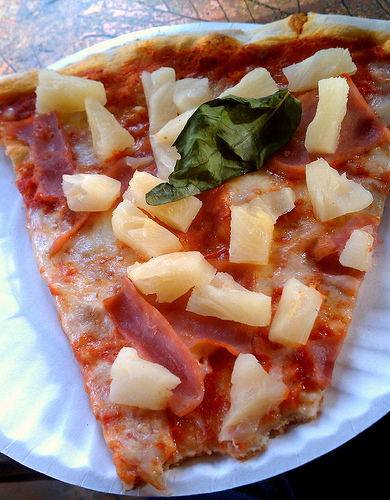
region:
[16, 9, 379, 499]
food on top of plate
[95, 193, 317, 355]
pineapple on top of pizza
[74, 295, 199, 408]
bacon on top of pizza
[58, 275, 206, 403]
canadien bacon on pizza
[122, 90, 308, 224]
green leaf on pizza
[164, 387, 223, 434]
red sauce on pizza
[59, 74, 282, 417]
toppings on a pizza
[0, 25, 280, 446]
pizza on a white paper plate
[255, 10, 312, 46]
white crust on end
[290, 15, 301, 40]
cheese on top of crust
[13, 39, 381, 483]
a large piece of pizza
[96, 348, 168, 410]
a small piece of some pineapple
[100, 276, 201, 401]
a small piece of some ham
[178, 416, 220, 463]
a little bit of tomato sauce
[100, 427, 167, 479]
a little bit of melted cheese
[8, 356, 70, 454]
the edges of a paper plate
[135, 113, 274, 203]
a small piece of some spinach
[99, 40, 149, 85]
a small piece of some crust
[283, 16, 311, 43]
the burnt part of the crust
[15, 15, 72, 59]
the design of a counter top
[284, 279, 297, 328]
chunk of pineapple on pizza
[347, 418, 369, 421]
pizza on white paper plate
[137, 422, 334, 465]
bites taken out of pizza slice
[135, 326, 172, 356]
slice of ham on pizza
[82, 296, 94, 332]
melted cheese on pizza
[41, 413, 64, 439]
paper plate has ridges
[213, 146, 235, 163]
piece of spinach on pizza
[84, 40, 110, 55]
dry crust of pizza slice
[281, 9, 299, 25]
brown spot on crust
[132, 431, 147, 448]
oily spot on cheese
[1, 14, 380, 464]
Pizza slice on the white paper plate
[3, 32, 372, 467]
Ham and pineapple toppings on the pizza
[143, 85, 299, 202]
Basil leaf on the pizza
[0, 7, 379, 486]
Half eaten pizza slice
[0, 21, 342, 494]
Brown table underneath the plate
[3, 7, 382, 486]
Thin crust pizza slice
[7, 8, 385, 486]
White paper plate underneath a pizza slice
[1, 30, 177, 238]
Red pizza sauce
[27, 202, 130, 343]
Cheese on the pizza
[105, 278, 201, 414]
A piece of ham and pineapple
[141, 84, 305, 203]
a wilted basil leaf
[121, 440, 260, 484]
a bite mark in a pizza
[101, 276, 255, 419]
a piece of cooked meat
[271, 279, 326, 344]
a small chunk of pineapple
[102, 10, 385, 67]
a pale pizza crust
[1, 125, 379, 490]
a white paper plate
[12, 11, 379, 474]
a slice of pizza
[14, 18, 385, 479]
pizza on a paper plate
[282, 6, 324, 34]
a crack in a pizza crust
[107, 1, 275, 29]
a design in the table